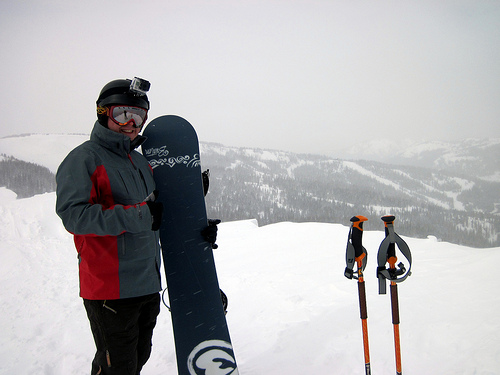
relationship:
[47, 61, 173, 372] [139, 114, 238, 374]
person holds board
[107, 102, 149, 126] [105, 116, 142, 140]
goggles on face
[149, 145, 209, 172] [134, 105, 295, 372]
sign on board